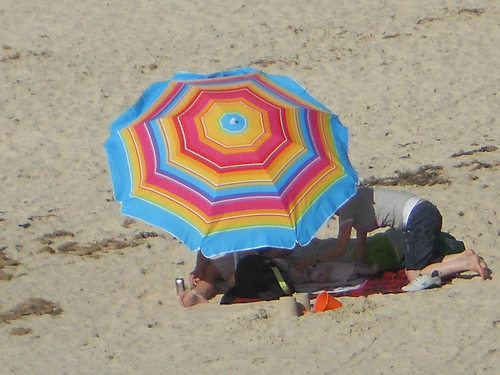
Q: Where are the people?
A: Under the umbrella.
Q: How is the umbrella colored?
A: Brightly.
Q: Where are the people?
A: Under beach umbrella.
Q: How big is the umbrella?
A: Huge.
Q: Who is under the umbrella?
A: Some people.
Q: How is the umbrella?
A: Colorful.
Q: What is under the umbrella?
A: Some people.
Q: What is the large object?
A: Umbrella.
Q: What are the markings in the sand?
A: Tracks.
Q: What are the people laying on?
A: Towel.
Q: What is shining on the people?
A: Sunlight.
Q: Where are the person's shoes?
A: On the towel.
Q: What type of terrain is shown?
A: Sand.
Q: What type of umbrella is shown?
A: Beach.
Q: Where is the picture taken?
A: The beach.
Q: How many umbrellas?
A: One.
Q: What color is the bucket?
A: Orange.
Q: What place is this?
A: A beach.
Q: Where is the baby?
A: Lying down.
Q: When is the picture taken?
A: Daytime.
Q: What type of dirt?
A: Sand.